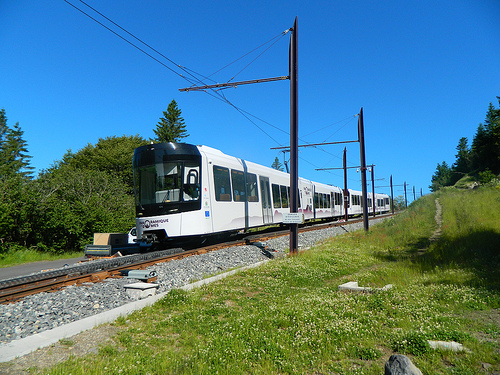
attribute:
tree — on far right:
[428, 161, 456, 193]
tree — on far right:
[450, 137, 477, 185]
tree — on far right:
[469, 121, 491, 173]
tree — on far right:
[482, 100, 499, 176]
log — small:
[378, 343, 429, 373]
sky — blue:
[312, 14, 473, 188]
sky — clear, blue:
[0, 0, 499, 148]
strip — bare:
[428, 193, 449, 256]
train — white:
[125, 136, 397, 268]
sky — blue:
[352, 15, 469, 90]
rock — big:
[380, 349, 425, 374]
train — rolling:
[127, 126, 377, 258]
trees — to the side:
[151, 99, 194, 141]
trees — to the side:
[0, 107, 130, 227]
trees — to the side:
[432, 157, 498, 179]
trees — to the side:
[458, 97, 498, 154]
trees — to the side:
[2, 221, 83, 256]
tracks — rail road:
[0, 208, 408, 306]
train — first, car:
[132, 140, 390, 247]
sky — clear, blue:
[1, 2, 499, 202]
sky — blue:
[330, 35, 461, 93]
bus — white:
[127, 140, 392, 242]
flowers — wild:
[249, 294, 396, 358]